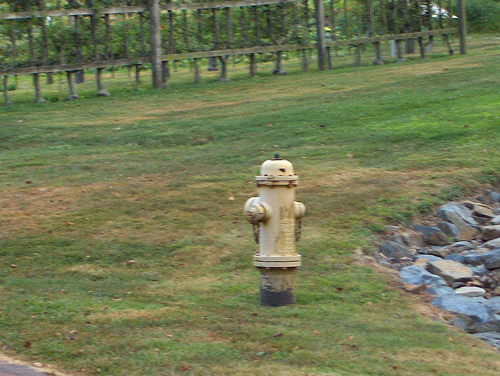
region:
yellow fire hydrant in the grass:
[238, 142, 315, 311]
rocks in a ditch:
[386, 172, 488, 345]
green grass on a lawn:
[77, 122, 274, 169]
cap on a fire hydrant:
[246, 199, 265, 226]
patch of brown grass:
[3, 180, 52, 227]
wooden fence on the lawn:
[3, 6, 272, 77]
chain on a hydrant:
[290, 215, 307, 246]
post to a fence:
[144, 1, 171, 93]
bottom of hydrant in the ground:
[253, 269, 301, 306]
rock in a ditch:
[428, 289, 491, 319]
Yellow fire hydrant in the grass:
[245, 153, 307, 308]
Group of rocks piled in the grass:
[376, 182, 498, 352]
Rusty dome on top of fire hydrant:
[255, 155, 299, 186]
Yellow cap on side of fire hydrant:
[244, 203, 265, 221]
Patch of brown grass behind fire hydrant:
[3, 154, 452, 250]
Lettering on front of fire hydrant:
[276, 213, 297, 255]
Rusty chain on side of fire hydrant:
[250, 219, 262, 243]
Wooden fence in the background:
[4, 1, 469, 105]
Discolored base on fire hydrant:
[260, 268, 294, 304]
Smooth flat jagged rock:
[426, 261, 476, 279]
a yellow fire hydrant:
[243, 153, 305, 305]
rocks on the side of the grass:
[385, 188, 497, 355]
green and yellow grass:
[15, 100, 228, 360]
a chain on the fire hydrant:
[250, 215, 258, 240]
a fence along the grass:
[7, 10, 477, 71]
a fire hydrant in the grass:
[245, 151, 306, 301]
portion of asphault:
[0, 355, 42, 375]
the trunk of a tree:
[145, 5, 162, 85]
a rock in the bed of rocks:
[432, 253, 473, 283]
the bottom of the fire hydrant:
[253, 257, 297, 302]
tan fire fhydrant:
[246, 141, 307, 283]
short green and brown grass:
[12, 168, 77, 206]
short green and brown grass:
[124, 229, 191, 282]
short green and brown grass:
[325, 314, 366, 340]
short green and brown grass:
[165, 326, 212, 359]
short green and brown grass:
[96, 279, 162, 321]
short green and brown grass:
[138, 159, 176, 218]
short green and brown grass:
[322, 89, 368, 130]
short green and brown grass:
[383, 68, 436, 112]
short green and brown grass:
[53, 133, 91, 175]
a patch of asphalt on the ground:
[0, 362, 57, 374]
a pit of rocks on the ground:
[365, 186, 498, 347]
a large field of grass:
[0, 33, 499, 375]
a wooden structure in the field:
[0, 0, 467, 106]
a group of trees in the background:
[455, 0, 499, 34]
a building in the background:
[405, 0, 457, 35]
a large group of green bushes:
[0, 0, 433, 77]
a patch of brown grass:
[0, 181, 105, 234]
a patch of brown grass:
[295, 166, 466, 189]